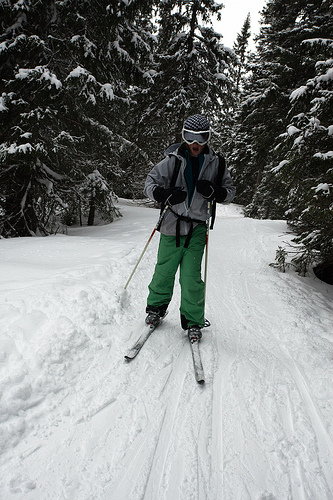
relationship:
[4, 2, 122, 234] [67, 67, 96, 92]
tree has snow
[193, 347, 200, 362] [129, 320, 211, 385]
snow on skis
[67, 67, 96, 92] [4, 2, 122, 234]
snow covers tree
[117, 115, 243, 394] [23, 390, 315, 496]
person skiing in snow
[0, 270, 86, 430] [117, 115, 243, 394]
mound next to person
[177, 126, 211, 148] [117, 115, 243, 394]
goggles on person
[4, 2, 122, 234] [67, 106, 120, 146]
tree has branches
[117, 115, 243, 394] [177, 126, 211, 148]
person has goggles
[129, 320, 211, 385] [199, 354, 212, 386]
skis have edge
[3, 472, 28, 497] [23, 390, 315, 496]
hole in snow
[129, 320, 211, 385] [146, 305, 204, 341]
skis are on feet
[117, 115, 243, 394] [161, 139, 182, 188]
person wears backpack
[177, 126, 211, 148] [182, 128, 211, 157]
goggles are on face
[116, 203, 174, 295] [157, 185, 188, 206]
pole in hand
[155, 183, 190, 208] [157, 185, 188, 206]
glove on hand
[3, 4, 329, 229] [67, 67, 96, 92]
trees have snow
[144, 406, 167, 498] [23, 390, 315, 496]
line of snow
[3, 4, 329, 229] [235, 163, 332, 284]
trees at edge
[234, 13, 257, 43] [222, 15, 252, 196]
top of tree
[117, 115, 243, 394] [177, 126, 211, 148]
person wearing goggles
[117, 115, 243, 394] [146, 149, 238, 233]
person wearing jacket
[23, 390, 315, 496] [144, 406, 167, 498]
snow has line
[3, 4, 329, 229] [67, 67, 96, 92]
trees covered in snow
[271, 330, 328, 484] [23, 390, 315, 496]
line in snow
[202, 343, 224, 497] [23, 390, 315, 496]
line in snow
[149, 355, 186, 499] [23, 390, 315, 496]
line in snow